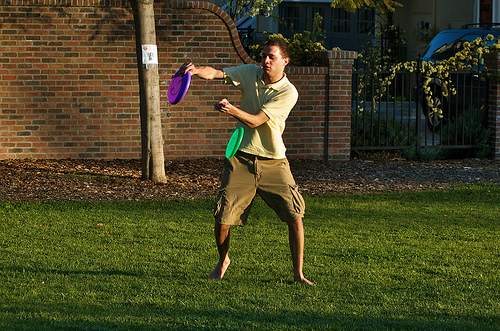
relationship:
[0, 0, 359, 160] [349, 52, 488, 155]
brick wall next to gate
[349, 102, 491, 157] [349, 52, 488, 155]
shrubs next to gate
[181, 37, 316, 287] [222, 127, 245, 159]
man playing with frisbee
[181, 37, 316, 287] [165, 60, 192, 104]
man playing with frisbee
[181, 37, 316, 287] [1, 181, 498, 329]
man standing on grass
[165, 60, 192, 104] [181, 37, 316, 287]
frisbee held by man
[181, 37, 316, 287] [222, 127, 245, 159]
man dropping frisbee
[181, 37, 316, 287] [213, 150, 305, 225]
man wearing shorts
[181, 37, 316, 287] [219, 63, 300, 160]
man wearing shirt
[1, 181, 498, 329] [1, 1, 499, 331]
grass inside of park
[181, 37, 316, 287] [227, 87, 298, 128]
man has arm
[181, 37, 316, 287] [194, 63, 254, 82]
man has arm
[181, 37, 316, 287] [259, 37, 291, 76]
man has head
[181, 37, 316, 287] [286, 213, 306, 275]
man has leg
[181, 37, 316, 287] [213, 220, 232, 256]
man has leg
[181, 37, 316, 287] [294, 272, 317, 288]
man has foot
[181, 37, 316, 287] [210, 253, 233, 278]
man has feet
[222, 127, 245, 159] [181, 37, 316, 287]
frisbee held by man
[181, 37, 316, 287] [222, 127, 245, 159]
man holding frisbee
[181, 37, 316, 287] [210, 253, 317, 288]
man has feet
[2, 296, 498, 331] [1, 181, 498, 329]
shadow cast on grass